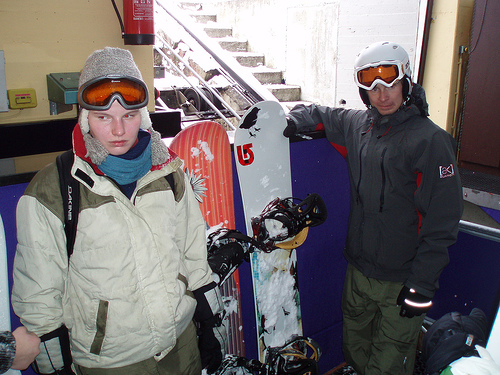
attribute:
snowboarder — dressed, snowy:
[4, 42, 231, 374]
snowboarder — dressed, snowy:
[284, 35, 470, 374]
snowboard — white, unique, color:
[232, 88, 317, 374]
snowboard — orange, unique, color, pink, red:
[158, 112, 255, 373]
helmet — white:
[350, 35, 417, 114]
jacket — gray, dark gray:
[286, 98, 480, 301]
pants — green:
[341, 256, 428, 374]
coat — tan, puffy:
[6, 109, 227, 374]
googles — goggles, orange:
[73, 74, 151, 114]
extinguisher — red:
[118, 1, 155, 52]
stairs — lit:
[175, 0, 318, 110]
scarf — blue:
[87, 132, 164, 187]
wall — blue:
[0, 109, 392, 371]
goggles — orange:
[350, 57, 404, 91]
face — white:
[77, 98, 149, 155]